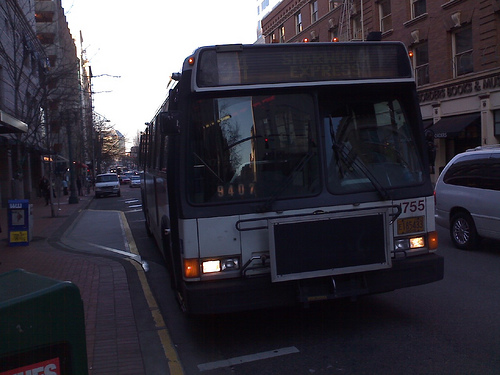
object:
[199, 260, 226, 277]
headlight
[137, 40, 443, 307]
bus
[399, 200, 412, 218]
number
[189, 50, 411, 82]
marquee display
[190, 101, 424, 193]
windshield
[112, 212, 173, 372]
yellow paint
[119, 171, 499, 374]
street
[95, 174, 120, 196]
van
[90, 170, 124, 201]
cars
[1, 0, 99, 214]
building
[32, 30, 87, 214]
trees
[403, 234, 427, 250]
headlight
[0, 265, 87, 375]
bin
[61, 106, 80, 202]
pole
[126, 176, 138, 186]
car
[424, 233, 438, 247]
signal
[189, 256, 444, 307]
bumper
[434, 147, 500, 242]
mini van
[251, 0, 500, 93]
building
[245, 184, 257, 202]
numbers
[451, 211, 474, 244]
tire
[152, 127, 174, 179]
window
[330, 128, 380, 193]
windshield wiper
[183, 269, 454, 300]
fender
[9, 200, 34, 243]
newspaper dispenser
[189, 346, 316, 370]
white stripe